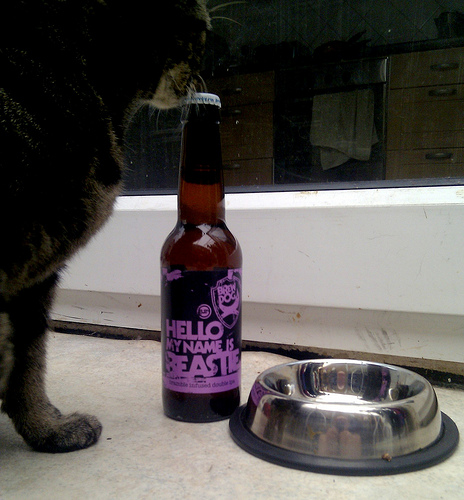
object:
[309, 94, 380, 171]
towel reflection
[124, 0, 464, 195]
window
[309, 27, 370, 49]
pans reflection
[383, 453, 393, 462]
crumb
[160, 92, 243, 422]
beer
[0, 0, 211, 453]
black cat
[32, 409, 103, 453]
paw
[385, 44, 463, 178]
dresser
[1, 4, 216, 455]
cat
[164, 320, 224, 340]
word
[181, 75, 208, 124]
whiskers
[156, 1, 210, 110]
face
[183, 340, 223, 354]
name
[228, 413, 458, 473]
base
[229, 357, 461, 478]
cat dish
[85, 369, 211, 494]
floor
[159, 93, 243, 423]
beer bottle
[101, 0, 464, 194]
pane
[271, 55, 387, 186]
door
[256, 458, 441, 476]
rim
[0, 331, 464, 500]
carpeting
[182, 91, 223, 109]
cap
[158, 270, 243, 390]
label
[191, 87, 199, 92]
nose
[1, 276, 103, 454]
leg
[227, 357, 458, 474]
bowl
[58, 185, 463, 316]
baseboard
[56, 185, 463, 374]
wall